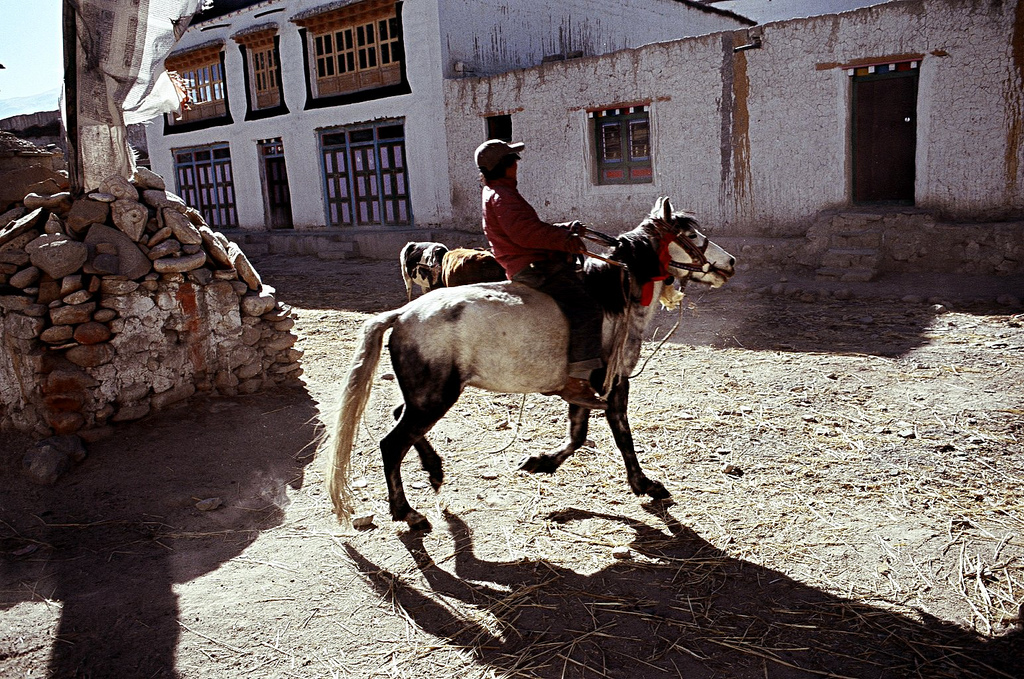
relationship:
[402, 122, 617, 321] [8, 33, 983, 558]
people enjoying outdoors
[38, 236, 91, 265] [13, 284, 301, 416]
rock in a structure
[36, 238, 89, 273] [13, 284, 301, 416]
rock in a structure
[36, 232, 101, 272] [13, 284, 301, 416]
rock in a structure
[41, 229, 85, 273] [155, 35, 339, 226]
rock in a structure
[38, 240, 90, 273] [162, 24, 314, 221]
rock in a structure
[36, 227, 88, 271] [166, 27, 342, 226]
rock in a structure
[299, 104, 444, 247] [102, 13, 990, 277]
window on building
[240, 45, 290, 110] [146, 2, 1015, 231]
window pane on building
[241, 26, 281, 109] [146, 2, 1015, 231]
window pane on building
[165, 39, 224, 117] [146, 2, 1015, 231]
window pane on building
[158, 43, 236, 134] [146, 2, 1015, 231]
window pane on building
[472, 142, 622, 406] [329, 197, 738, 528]
man riding horse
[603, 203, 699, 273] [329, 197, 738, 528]
mane of horse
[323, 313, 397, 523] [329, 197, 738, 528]
tail of horse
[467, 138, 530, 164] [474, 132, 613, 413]
hat worn by man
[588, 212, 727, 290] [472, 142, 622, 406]
reins held by man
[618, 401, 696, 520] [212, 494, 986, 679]
mostly black right horse leg touching ground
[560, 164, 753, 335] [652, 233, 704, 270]
mostly white horses head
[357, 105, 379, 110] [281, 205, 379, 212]
glass window pane on building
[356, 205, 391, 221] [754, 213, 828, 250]
glass window pane on building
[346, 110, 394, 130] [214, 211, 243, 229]
glass window pane on building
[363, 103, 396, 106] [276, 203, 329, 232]
glass window pane on building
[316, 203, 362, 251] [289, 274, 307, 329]
glass window pane on building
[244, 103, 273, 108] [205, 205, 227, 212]
glass window pane on building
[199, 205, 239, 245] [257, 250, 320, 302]
glass window pane on building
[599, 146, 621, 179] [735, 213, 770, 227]
glass window pane on building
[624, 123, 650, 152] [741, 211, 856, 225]
glass window pane on building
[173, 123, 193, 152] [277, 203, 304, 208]
glass window pane on building